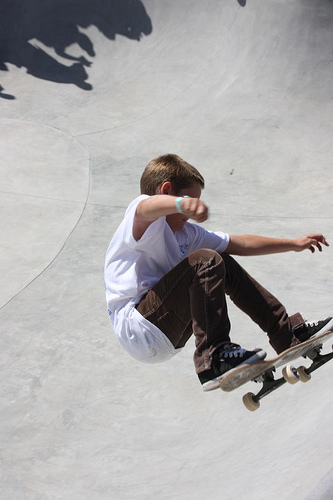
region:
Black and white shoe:
[186, 339, 258, 384]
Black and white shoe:
[270, 323, 330, 338]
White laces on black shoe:
[217, 343, 256, 365]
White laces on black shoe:
[299, 313, 318, 326]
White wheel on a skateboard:
[238, 390, 261, 417]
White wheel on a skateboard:
[278, 363, 300, 388]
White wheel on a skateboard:
[296, 363, 306, 383]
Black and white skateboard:
[207, 349, 324, 403]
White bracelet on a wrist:
[172, 191, 194, 219]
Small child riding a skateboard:
[105, 134, 312, 423]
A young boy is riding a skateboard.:
[101, 150, 332, 411]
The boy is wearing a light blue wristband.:
[174, 194, 186, 215]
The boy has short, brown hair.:
[139, 153, 205, 194]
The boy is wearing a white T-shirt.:
[104, 193, 229, 363]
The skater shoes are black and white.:
[196, 341, 265, 392]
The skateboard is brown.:
[220, 332, 331, 391]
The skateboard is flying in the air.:
[219, 330, 332, 411]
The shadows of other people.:
[0, 0, 152, 99]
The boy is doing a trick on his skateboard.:
[103, 153, 331, 410]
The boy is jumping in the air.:
[103, 153, 331, 409]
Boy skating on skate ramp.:
[100, 150, 331, 413]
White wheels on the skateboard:
[241, 362, 318, 412]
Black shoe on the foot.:
[199, 338, 266, 395]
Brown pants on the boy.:
[97, 149, 315, 383]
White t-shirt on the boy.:
[95, 144, 231, 363]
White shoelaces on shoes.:
[216, 340, 251, 362]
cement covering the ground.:
[1, 0, 331, 498]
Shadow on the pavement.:
[0, 0, 156, 110]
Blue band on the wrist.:
[169, 191, 191, 218]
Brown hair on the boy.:
[134, 150, 205, 235]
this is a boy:
[102, 144, 328, 387]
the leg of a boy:
[140, 247, 252, 395]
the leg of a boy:
[224, 251, 331, 352]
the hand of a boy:
[106, 172, 222, 250]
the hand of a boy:
[209, 201, 327, 271]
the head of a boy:
[129, 156, 214, 234]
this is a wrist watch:
[172, 189, 188, 222]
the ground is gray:
[91, 427, 169, 477]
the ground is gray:
[22, 292, 87, 403]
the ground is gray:
[174, 413, 291, 491]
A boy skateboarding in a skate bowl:
[91, 147, 327, 410]